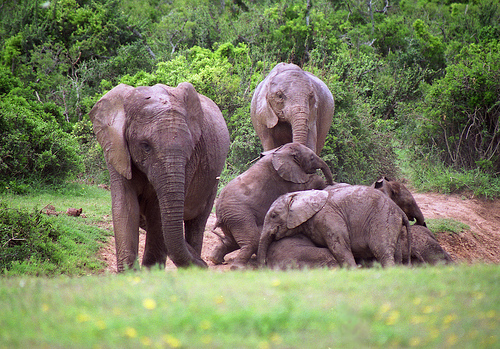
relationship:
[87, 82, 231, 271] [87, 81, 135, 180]
elephant has ear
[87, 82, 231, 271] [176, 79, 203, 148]
elephant has ear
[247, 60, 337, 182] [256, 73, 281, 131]
elephant has ear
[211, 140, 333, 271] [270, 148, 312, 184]
elephant has ear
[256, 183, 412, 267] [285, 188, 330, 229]
elephant has ear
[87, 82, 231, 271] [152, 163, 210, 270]
elephant has trunk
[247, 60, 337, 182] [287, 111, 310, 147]
elephant has trunk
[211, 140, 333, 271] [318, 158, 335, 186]
elephant has trunk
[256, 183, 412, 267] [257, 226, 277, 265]
elephant has trunk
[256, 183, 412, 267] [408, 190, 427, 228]
elephant has trunk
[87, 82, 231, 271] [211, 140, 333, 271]
elephant looking at elephant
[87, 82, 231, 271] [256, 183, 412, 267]
elephant looking at elephant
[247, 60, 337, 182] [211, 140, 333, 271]
elephant looking at elephant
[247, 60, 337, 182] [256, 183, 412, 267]
elephant looking at elephant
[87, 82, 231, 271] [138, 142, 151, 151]
elephant has eye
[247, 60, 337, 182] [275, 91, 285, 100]
elephant has eye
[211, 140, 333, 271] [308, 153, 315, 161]
elephant has eye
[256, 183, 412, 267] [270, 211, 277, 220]
elephant has eye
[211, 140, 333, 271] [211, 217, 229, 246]
elephant has tail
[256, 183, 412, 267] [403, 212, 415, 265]
elephant has tail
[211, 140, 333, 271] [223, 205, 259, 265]
elephant has leg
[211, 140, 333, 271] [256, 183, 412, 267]
elephant laying on elephant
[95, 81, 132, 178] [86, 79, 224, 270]
ear on elephant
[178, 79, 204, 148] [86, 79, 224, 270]
ear on elephant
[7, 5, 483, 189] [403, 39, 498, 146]
forest filled with tree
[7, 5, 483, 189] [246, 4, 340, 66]
forest filled with tree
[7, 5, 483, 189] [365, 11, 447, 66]
forest filled with tree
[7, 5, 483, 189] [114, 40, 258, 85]
forest filled with tree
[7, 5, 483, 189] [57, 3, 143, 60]
forest filled with tree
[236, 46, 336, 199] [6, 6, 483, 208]
elephant in woods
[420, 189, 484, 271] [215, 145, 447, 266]
dirt to side of elephants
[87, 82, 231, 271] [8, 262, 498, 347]
elephant in grassy area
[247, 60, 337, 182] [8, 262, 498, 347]
elephant in grassy area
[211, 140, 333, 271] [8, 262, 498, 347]
elephant in grassy area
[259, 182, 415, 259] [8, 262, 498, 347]
elephant in grassy area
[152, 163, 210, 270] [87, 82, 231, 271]
trunk of elephant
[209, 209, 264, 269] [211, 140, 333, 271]
legs of elephant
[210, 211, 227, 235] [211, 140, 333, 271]
tail of elephant